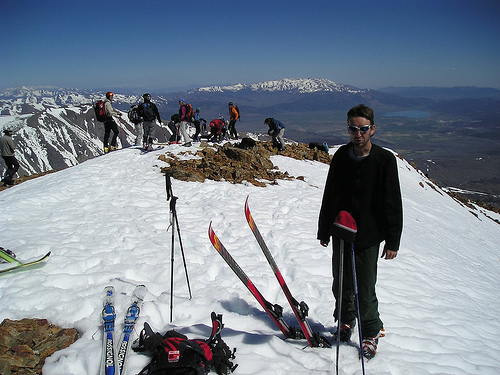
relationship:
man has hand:
[322, 106, 404, 360] [376, 246, 401, 261]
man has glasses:
[322, 106, 404, 360] [347, 125, 372, 132]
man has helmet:
[95, 88, 125, 154] [106, 91, 115, 98]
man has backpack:
[95, 88, 125, 154] [91, 96, 107, 124]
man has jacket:
[226, 97, 242, 141] [227, 107, 241, 119]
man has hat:
[177, 96, 196, 149] [178, 98, 186, 104]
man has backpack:
[177, 96, 196, 149] [187, 102, 195, 122]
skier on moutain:
[322, 106, 404, 360] [2, 136, 499, 371]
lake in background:
[383, 108, 431, 118] [15, 87, 497, 125]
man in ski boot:
[322, 106, 404, 360] [329, 311, 355, 339]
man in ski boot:
[322, 106, 404, 360] [360, 325, 387, 358]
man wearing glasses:
[322, 106, 404, 360] [347, 125, 372, 132]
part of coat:
[349, 166, 376, 200] [329, 143, 396, 242]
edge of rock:
[10, 320, 78, 337] [6, 319, 89, 374]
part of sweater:
[349, 166, 376, 200] [329, 143, 396, 242]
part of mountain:
[161, 138, 263, 179] [2, 136, 499, 371]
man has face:
[322, 106, 404, 360] [346, 105, 374, 146]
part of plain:
[440, 152, 462, 162] [293, 107, 498, 173]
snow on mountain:
[237, 80, 337, 87] [208, 80, 375, 105]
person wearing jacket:
[95, 88, 125, 154] [104, 100, 117, 116]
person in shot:
[2, 130, 26, 186] [1, 2, 495, 370]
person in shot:
[95, 88, 125, 154] [1, 2, 495, 370]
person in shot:
[138, 96, 162, 149] [1, 2, 495, 370]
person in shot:
[177, 96, 196, 149] [1, 2, 495, 370]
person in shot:
[210, 113, 226, 139] [1, 2, 495, 370]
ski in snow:
[208, 217, 248, 291] [26, 156, 494, 367]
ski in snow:
[244, 194, 307, 273] [26, 156, 494, 367]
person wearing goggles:
[322, 106, 404, 360] [347, 125, 372, 132]